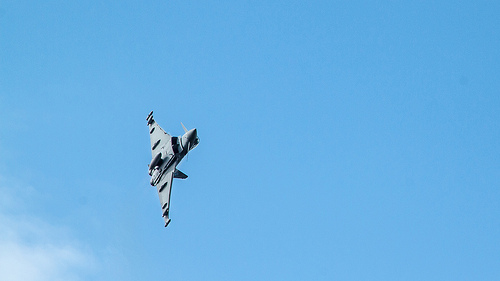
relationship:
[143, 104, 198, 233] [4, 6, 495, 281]
jet in sky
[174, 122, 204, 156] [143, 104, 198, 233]
front of jet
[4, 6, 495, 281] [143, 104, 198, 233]
sky behind jet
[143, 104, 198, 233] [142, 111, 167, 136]
jet has wing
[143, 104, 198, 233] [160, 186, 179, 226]
jet has wing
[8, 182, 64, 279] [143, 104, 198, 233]
cloud behind jet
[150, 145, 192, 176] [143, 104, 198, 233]
body of jet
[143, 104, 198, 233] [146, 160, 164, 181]
jet has tail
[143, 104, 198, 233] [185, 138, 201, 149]
jet has cockpit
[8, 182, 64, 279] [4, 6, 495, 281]
cloud in sky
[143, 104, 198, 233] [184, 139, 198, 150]
jet has window